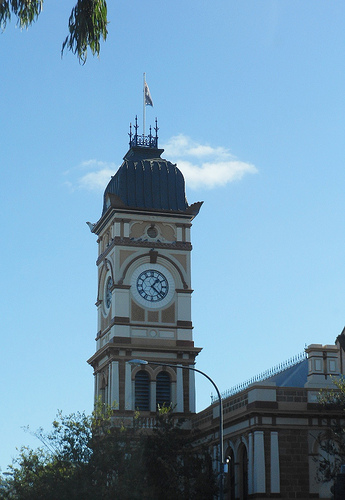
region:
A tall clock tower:
[84, 71, 202, 489]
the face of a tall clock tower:
[129, 263, 176, 311]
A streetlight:
[126, 357, 227, 498]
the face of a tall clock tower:
[104, 275, 113, 308]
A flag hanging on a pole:
[142, 71, 152, 135]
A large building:
[192, 329, 342, 498]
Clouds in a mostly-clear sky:
[61, 130, 258, 194]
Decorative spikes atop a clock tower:
[126, 114, 160, 148]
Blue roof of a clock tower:
[101, 146, 189, 214]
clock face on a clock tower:
[103, 268, 167, 308]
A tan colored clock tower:
[86, 63, 213, 412]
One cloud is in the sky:
[65, 124, 261, 213]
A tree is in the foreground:
[2, 398, 223, 498]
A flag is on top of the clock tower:
[132, 68, 159, 137]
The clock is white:
[131, 258, 176, 313]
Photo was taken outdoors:
[0, 12, 344, 491]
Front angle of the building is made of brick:
[278, 429, 307, 499]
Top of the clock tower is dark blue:
[104, 153, 198, 214]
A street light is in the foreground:
[123, 355, 236, 498]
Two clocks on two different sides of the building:
[96, 255, 185, 325]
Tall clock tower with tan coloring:
[69, 67, 207, 496]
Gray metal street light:
[124, 359, 215, 379]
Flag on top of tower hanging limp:
[129, 50, 158, 147]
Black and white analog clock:
[132, 262, 171, 306]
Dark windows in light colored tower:
[123, 367, 179, 411]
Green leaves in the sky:
[0, 1, 118, 64]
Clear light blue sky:
[177, 10, 338, 72]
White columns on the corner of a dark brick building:
[232, 376, 295, 489]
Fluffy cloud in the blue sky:
[197, 131, 249, 195]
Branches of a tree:
[23, 419, 208, 498]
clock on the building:
[128, 263, 176, 309]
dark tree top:
[1, 403, 217, 497]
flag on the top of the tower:
[140, 70, 156, 134]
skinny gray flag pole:
[139, 72, 146, 137]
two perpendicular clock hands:
[148, 276, 165, 296]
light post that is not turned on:
[129, 357, 237, 490]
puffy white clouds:
[59, 113, 249, 206]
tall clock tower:
[65, 120, 218, 437]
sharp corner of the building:
[198, 198, 205, 206]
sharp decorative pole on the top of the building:
[152, 115, 159, 135]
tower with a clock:
[57, 180, 235, 377]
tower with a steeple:
[104, 59, 182, 177]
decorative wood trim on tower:
[75, 196, 227, 399]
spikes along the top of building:
[196, 351, 310, 383]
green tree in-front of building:
[56, 432, 149, 492]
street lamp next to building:
[119, 348, 250, 494]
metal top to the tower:
[112, 156, 197, 207]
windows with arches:
[122, 362, 186, 428]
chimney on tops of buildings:
[302, 335, 337, 399]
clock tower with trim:
[123, 243, 200, 347]